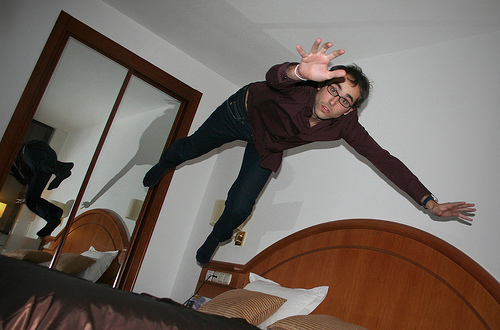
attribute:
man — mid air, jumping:
[143, 39, 477, 266]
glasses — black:
[323, 80, 356, 111]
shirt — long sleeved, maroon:
[247, 61, 432, 205]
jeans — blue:
[151, 82, 273, 245]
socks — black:
[143, 161, 219, 266]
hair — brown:
[328, 63, 375, 110]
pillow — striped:
[198, 289, 288, 326]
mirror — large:
[0, 9, 203, 291]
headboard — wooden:
[195, 218, 499, 329]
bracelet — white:
[294, 63, 308, 83]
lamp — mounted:
[210, 199, 247, 246]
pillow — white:
[240, 270, 330, 329]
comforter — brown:
[0, 254, 264, 329]